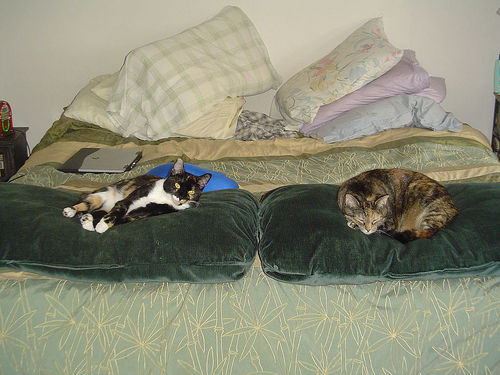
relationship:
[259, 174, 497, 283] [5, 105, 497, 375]
pillow on top of bed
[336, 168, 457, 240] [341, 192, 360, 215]
cat has ear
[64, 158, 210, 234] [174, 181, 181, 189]
calico cat has eye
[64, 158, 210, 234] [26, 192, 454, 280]
calico cat on pillow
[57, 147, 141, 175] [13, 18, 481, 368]
laptop on bed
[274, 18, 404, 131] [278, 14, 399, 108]
pillow with case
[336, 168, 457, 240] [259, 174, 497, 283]
cat on a pillow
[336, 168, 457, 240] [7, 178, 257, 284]
cat on pillow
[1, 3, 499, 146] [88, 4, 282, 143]
wall behind pillow